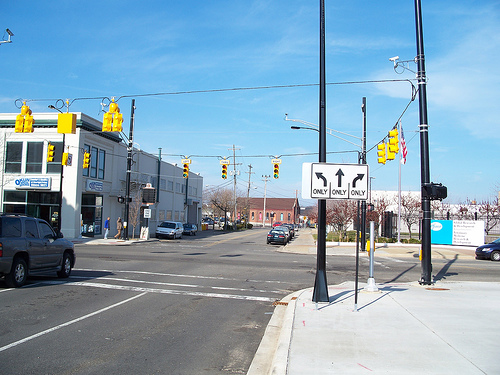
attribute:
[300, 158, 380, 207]
sign — below, black, here, white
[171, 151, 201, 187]
light — below, hanging, high, on, yellow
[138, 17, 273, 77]
sky — high, bright, clear, clean, here, close, light, blue, above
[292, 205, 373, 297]
pole — here, black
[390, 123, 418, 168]
flag — american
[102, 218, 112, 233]
shirt — blue